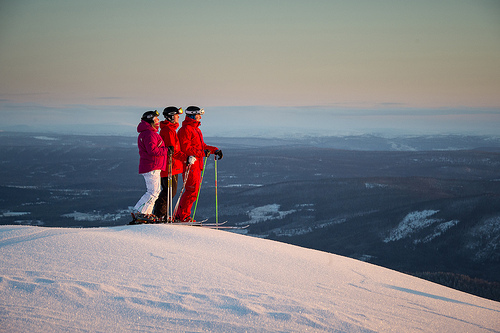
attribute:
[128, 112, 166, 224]
skier — standing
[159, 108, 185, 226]
skier — standing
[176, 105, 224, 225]
skier — standing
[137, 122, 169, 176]
coat — pink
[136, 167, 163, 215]
pants — white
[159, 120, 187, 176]
coat — red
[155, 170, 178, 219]
pants — black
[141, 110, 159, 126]
helmet — black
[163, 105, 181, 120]
helmet — black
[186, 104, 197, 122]
helmet — black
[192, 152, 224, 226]
ski poles — green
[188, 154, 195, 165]
glove — white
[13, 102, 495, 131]
clouds — low, hanging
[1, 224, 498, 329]
mountain — white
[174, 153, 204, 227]
pants — red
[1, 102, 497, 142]
mountain — cloudy